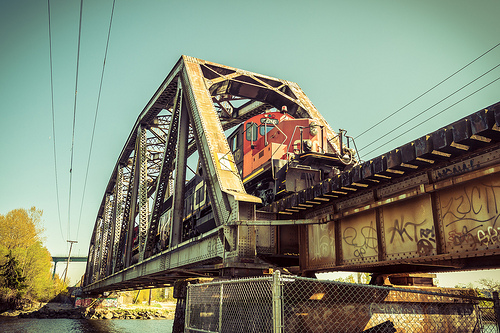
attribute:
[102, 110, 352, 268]
train — red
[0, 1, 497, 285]
sky — blue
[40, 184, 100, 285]
cloud — white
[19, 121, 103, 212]
cloud — white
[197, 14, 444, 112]
sky — blue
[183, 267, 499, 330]
fence — metal, chain link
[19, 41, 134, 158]
cloud — white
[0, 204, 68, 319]
tree — green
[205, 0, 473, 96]
sky — blue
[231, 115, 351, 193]
traincar — red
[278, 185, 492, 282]
bridge — vandalized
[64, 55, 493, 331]
train bridge — metal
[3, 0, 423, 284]
sky — blue